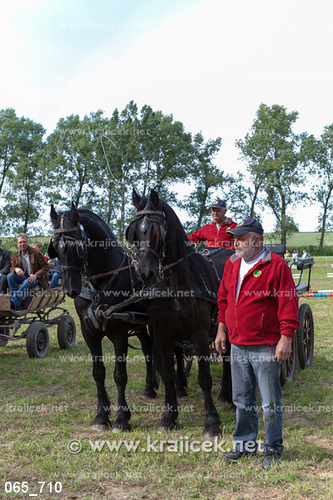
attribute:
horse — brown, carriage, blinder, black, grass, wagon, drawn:
[97, 202, 202, 376]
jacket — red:
[202, 268, 279, 333]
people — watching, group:
[0, 75, 309, 415]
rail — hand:
[173, 225, 247, 259]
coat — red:
[263, 262, 314, 313]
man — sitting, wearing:
[9, 205, 64, 301]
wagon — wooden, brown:
[1, 262, 96, 341]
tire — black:
[48, 316, 84, 328]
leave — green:
[124, 130, 223, 173]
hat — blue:
[232, 214, 283, 248]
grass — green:
[9, 439, 118, 469]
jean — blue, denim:
[215, 363, 282, 448]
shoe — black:
[223, 437, 319, 449]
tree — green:
[29, 118, 190, 155]